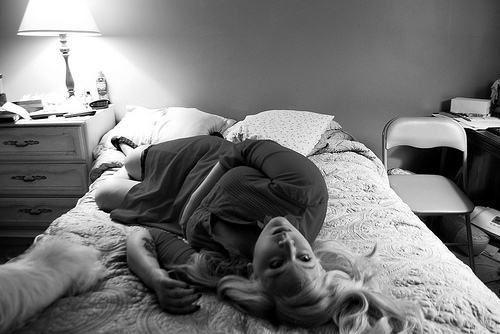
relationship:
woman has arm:
[92, 132, 415, 332] [116, 220, 202, 317]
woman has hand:
[92, 132, 415, 332] [146, 268, 205, 317]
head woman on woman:
[250, 216, 362, 331] [93, 117, 366, 324]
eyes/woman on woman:
[248, 230, 327, 301] [87, 124, 402, 310]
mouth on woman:
[264, 224, 297, 240] [74, 73, 342, 332]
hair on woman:
[329, 246, 397, 333] [93, 137, 336, 307]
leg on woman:
[111, 135, 226, 180] [92, 132, 415, 332]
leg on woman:
[93, 164, 184, 211] [92, 132, 415, 332]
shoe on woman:
[110, 133, 135, 146] [92, 132, 415, 332]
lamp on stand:
[11, 1, 97, 108] [6, 100, 133, 250]